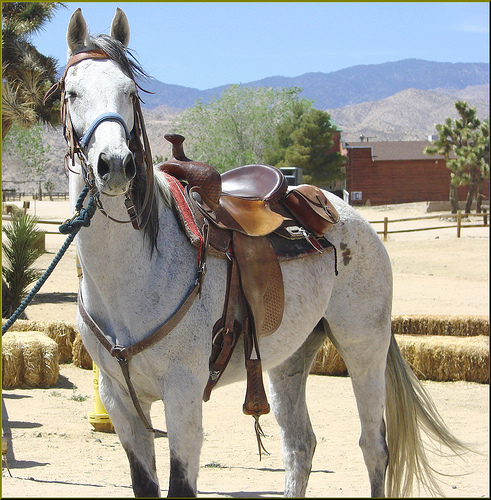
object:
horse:
[59, 4, 490, 498]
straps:
[114, 220, 211, 362]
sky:
[3, 0, 489, 92]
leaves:
[273, 110, 283, 121]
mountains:
[3, 56, 490, 193]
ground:
[1, 192, 488, 499]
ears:
[65, 7, 90, 52]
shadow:
[0, 392, 338, 499]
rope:
[0, 180, 100, 338]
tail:
[384, 325, 487, 498]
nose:
[93, 150, 138, 184]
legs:
[323, 301, 391, 499]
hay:
[0, 311, 490, 392]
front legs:
[158, 382, 205, 500]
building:
[274, 108, 491, 208]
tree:
[424, 99, 489, 215]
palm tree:
[0, 0, 66, 148]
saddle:
[152, 133, 341, 460]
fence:
[0, 210, 489, 245]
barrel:
[88, 358, 118, 431]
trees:
[254, 99, 352, 186]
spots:
[165, 448, 195, 499]